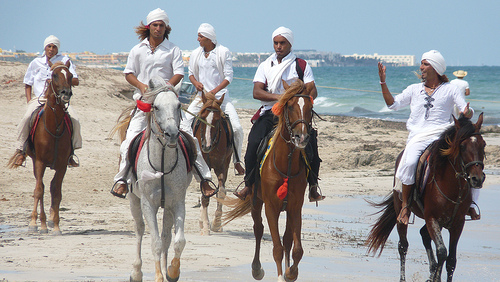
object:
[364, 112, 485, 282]
horse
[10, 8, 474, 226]
group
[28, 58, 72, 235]
horse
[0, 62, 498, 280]
beach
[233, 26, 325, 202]
man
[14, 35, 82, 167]
man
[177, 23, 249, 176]
man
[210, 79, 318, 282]
horse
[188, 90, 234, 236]
horse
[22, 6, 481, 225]
people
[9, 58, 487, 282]
horses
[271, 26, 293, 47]
turban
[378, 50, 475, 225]
lady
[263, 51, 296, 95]
scarf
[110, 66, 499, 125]
water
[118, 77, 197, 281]
horse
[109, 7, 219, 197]
man